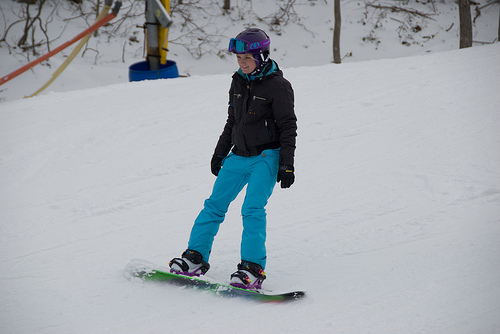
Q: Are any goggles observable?
A: Yes, there are goggles.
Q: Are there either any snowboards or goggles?
A: Yes, there are goggles.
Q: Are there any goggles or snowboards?
A: Yes, there are goggles.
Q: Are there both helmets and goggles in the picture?
A: Yes, there are both goggles and a helmet.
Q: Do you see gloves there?
A: Yes, there are gloves.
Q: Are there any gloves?
A: Yes, there are gloves.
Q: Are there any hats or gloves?
A: Yes, there are gloves.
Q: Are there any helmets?
A: Yes, there is a helmet.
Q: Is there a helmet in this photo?
A: Yes, there is a helmet.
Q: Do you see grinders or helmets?
A: Yes, there is a helmet.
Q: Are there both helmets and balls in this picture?
A: No, there is a helmet but no balls.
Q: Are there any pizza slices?
A: No, there are no pizza slices.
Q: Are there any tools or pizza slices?
A: No, there are no pizza slices or tools.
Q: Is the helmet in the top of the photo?
A: Yes, the helmet is in the top of the image.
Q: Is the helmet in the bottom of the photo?
A: No, the helmet is in the top of the image.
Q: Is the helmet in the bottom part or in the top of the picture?
A: The helmet is in the top of the image.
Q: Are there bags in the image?
A: No, there are no bags.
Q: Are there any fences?
A: No, there are no fences.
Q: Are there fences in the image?
A: No, there are no fences.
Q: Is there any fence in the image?
A: No, there are no fences.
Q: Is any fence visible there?
A: No, there are no fences.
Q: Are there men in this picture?
A: No, there are no men.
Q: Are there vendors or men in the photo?
A: No, there are no men or vendors.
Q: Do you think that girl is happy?
A: Yes, the girl is happy.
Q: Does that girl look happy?
A: Yes, the girl is happy.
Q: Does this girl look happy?
A: Yes, the girl is happy.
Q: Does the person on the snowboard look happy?
A: Yes, the girl is happy.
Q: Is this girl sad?
A: No, the girl is happy.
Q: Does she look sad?
A: No, the girl is happy.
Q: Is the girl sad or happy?
A: The girl is happy.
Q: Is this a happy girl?
A: Yes, this is a happy girl.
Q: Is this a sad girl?
A: No, this is a happy girl.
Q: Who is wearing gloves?
A: The girl is wearing gloves.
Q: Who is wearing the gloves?
A: The girl is wearing gloves.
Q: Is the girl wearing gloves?
A: Yes, the girl is wearing gloves.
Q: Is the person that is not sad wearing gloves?
A: Yes, the girl is wearing gloves.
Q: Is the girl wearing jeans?
A: No, the girl is wearing gloves.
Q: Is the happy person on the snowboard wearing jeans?
A: No, the girl is wearing gloves.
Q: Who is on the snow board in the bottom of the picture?
A: The girl is on the snowboard.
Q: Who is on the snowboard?
A: The girl is on the snowboard.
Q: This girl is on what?
A: The girl is on the snowboard.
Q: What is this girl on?
A: The girl is on the snowboard.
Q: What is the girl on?
A: The girl is on the snowboard.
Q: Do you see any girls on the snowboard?
A: Yes, there is a girl on the snowboard.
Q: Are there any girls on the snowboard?
A: Yes, there is a girl on the snowboard.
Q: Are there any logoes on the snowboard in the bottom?
A: No, there is a girl on the snowboard.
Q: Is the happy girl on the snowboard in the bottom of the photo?
A: Yes, the girl is on the snowboard.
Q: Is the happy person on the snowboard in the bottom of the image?
A: Yes, the girl is on the snowboard.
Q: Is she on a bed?
A: No, the girl is on the snowboard.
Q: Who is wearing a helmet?
A: The girl is wearing a helmet.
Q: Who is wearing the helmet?
A: The girl is wearing a helmet.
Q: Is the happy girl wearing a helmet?
A: Yes, the girl is wearing a helmet.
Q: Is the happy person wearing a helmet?
A: Yes, the girl is wearing a helmet.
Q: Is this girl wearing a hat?
A: No, the girl is wearing a helmet.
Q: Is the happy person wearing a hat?
A: No, the girl is wearing a helmet.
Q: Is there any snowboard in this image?
A: Yes, there is a snowboard.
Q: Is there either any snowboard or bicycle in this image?
A: Yes, there is a snowboard.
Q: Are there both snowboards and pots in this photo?
A: No, there is a snowboard but no pots.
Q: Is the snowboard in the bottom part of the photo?
A: Yes, the snowboard is in the bottom of the image.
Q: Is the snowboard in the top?
A: No, the snowboard is in the bottom of the image.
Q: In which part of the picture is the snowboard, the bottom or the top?
A: The snowboard is in the bottom of the image.